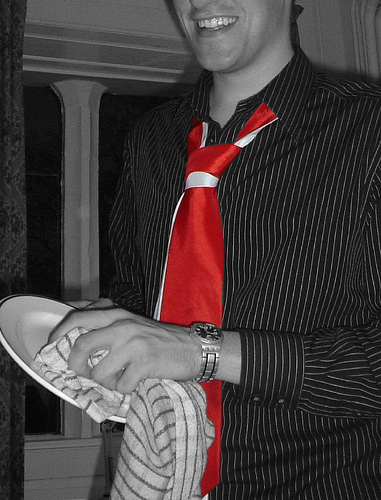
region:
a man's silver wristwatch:
[187, 319, 224, 382]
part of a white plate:
[0, 291, 130, 424]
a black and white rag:
[29, 327, 217, 498]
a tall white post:
[48, 78, 110, 301]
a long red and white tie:
[151, 101, 278, 498]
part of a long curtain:
[1, 0, 30, 498]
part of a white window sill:
[20, 435, 112, 489]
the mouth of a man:
[189, 15, 242, 37]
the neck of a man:
[204, 21, 292, 132]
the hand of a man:
[42, 304, 203, 391]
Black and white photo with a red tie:
[21, 5, 376, 494]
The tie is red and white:
[169, 94, 290, 482]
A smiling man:
[161, 0, 310, 82]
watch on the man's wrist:
[178, 313, 236, 390]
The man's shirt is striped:
[97, 56, 358, 488]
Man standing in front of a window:
[0, 48, 376, 491]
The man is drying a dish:
[3, 275, 245, 482]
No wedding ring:
[104, 343, 142, 370]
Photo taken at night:
[0, 94, 204, 422]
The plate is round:
[1, 285, 157, 440]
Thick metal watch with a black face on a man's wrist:
[173, 308, 230, 404]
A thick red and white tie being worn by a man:
[124, 98, 291, 476]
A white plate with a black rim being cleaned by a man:
[2, 267, 168, 462]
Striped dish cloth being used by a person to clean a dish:
[32, 315, 228, 498]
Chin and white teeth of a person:
[174, 6, 250, 52]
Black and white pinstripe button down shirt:
[225, 141, 342, 375]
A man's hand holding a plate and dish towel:
[58, 305, 180, 383]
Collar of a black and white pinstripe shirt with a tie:
[183, 66, 295, 179]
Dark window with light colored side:
[23, 84, 100, 297]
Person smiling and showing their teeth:
[148, 0, 314, 71]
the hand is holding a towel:
[1, 272, 268, 497]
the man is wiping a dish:
[2, 5, 374, 498]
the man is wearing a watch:
[179, 312, 230, 381]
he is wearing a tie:
[145, 101, 233, 494]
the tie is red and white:
[157, 103, 229, 497]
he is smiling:
[182, 10, 267, 45]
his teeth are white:
[186, 8, 242, 30]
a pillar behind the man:
[42, 68, 100, 441]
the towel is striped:
[29, 306, 212, 496]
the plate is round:
[0, 288, 168, 422]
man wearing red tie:
[150, 98, 286, 315]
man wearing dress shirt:
[180, 18, 378, 433]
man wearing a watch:
[92, 92, 338, 409]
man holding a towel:
[25, 60, 360, 432]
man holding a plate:
[23, 12, 331, 481]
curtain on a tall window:
[11, 25, 21, 287]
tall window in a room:
[28, 92, 62, 296]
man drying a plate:
[86, 4, 345, 481]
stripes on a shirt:
[316, 159, 374, 333]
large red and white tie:
[163, 105, 246, 312]